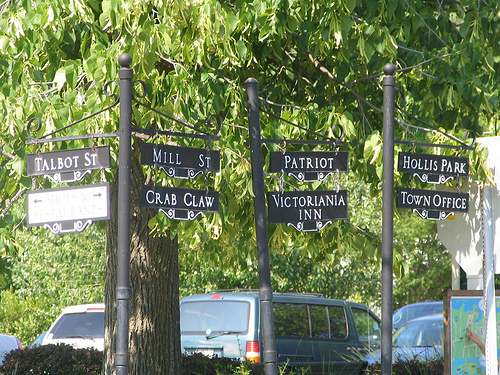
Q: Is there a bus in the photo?
A: No, there are no buses.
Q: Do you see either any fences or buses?
A: No, there are no buses or fences.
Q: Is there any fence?
A: No, there are no fences.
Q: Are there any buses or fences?
A: No, there are no fences or buses.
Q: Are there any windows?
A: Yes, there is a window.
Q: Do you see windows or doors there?
A: Yes, there is a window.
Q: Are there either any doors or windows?
A: Yes, there is a window.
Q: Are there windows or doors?
A: Yes, there is a window.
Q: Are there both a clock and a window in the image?
A: No, there is a window but no clocks.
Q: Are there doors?
A: No, there are no doors.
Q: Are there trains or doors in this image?
A: No, there are no doors or trains.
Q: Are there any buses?
A: No, there are no buses.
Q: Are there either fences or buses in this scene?
A: No, there are no buses or fences.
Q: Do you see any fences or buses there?
A: No, there are no buses or fences.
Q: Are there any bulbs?
A: No, there are no bulbs.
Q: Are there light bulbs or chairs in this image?
A: No, there are no light bulbs or chairs.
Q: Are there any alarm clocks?
A: No, there are no alarm clocks.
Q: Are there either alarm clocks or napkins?
A: No, there are no alarm clocks or napkins.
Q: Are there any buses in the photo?
A: No, there are no buses.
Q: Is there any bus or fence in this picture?
A: No, there are no buses or fences.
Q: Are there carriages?
A: No, there are no carriages.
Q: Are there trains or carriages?
A: No, there are no carriages or trains.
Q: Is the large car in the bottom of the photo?
A: Yes, the car is in the bottom of the image.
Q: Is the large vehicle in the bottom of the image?
A: Yes, the car is in the bottom of the image.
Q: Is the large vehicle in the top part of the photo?
A: No, the car is in the bottom of the image.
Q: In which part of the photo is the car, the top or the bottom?
A: The car is in the bottom of the image.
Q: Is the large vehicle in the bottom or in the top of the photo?
A: The car is in the bottom of the image.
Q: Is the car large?
A: Yes, the car is large.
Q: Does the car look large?
A: Yes, the car is large.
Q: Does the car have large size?
A: Yes, the car is large.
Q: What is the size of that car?
A: The car is large.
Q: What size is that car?
A: The car is large.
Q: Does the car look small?
A: No, the car is large.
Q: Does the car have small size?
A: No, the car is large.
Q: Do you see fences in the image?
A: No, there are no fences.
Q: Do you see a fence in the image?
A: No, there are no fences.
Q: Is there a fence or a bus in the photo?
A: No, there are no fences or buses.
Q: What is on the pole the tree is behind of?
A: The sign is on the pole.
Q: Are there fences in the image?
A: No, there are no fences.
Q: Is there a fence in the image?
A: No, there are no fences.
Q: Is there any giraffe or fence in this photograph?
A: No, there are no fences or giraffes.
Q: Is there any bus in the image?
A: No, there are no buses.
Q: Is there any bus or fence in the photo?
A: No, there are no buses or fences.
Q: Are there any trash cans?
A: No, there are no trash cans.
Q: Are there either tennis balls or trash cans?
A: No, there are no trash cans or tennis balls.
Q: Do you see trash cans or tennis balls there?
A: No, there are no trash cans or tennis balls.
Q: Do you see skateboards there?
A: No, there are no skateboards.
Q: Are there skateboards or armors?
A: No, there are no skateboards or armors.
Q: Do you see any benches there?
A: No, there are no benches.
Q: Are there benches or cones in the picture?
A: No, there are no benches or cones.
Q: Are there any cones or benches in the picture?
A: No, there are no benches or cones.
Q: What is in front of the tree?
A: The pole is in front of the tree.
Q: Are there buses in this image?
A: No, there are no buses.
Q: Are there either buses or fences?
A: No, there are no buses or fences.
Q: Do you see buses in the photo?
A: No, there are no buses.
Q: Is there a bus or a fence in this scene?
A: No, there are no buses or fences.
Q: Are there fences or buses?
A: No, there are no buses or fences.